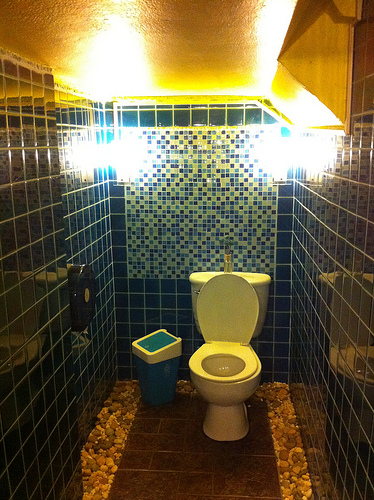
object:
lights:
[69, 141, 102, 172]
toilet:
[187, 270, 273, 443]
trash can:
[132, 328, 183, 405]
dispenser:
[68, 262, 98, 334]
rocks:
[105, 427, 115, 436]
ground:
[71, 378, 311, 500]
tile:
[160, 293, 177, 309]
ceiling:
[0, 0, 364, 133]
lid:
[196, 272, 260, 344]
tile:
[178, 471, 215, 494]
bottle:
[224, 253, 233, 275]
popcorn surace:
[0, 0, 265, 96]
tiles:
[124, 124, 279, 283]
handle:
[193, 290, 200, 294]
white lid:
[132, 328, 184, 365]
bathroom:
[0, 0, 373, 500]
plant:
[218, 234, 235, 255]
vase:
[224, 254, 233, 274]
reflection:
[319, 270, 374, 448]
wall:
[286, 0, 374, 499]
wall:
[101, 98, 296, 387]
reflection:
[296, 132, 339, 184]